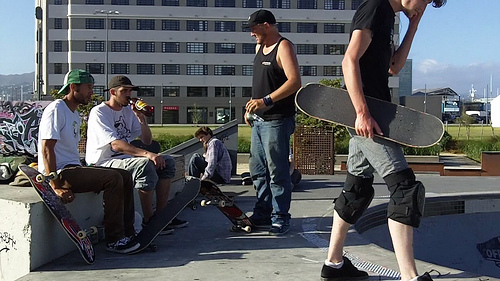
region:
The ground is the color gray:
[108, 253, 315, 279]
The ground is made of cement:
[173, 228, 289, 279]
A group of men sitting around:
[11, 0, 473, 279]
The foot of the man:
[310, 246, 374, 279]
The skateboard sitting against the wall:
[15, 155, 102, 270]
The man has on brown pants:
[56, 158, 142, 243]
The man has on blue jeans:
[246, 105, 301, 214]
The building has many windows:
[39, 4, 243, 87]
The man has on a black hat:
[235, 2, 281, 33]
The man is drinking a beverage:
[118, 92, 161, 118]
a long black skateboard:
[295, 83, 447, 151]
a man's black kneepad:
[377, 166, 430, 230]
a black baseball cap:
[237, 10, 279, 30]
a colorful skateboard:
[18, 162, 105, 263]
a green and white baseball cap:
[54, 67, 96, 102]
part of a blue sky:
[443, 15, 498, 46]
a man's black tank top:
[245, 35, 301, 115]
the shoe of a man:
[317, 258, 370, 278]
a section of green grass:
[447, 119, 494, 139]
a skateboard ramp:
[395, 200, 498, 267]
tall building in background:
[34, 10, 414, 115]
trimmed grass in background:
[172, 122, 499, 164]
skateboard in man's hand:
[322, 75, 444, 152]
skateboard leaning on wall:
[25, 152, 123, 254]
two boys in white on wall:
[42, 59, 182, 229]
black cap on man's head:
[242, 12, 287, 35]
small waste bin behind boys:
[292, 119, 348, 174]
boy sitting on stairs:
[178, 115, 238, 202]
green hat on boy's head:
[56, 57, 105, 89]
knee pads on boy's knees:
[330, 171, 451, 223]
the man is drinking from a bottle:
[93, 61, 183, 171]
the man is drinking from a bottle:
[91, 56, 205, 235]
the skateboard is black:
[260, 60, 487, 195]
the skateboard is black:
[123, 183, 264, 268]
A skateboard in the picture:
[297, 78, 451, 146]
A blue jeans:
[242, 125, 297, 218]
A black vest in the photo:
[245, 40, 303, 121]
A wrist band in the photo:
[257, 81, 276, 111]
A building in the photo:
[139, 9, 236, 88]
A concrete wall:
[0, 189, 52, 262]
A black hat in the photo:
[107, 67, 133, 88]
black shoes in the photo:
[317, 255, 438, 280]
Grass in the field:
[443, 118, 497, 135]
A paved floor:
[200, 238, 283, 277]